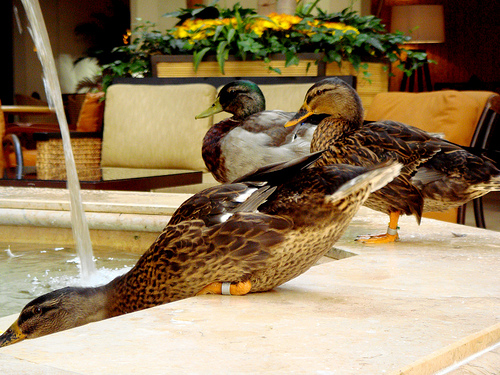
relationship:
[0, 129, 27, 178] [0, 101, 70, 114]
stand on table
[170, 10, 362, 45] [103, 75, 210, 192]
flowers on chair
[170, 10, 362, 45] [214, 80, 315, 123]
flowers on chair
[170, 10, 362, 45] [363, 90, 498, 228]
flowers on chair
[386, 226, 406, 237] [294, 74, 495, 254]
tag on duck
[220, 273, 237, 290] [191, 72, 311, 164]
tag on duck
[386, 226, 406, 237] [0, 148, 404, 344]
tag on duck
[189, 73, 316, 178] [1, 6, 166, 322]
duck standing by fountain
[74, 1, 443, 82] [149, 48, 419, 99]
greenery inside planter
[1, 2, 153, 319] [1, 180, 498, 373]
water in swimming pool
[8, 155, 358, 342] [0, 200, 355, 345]
duck drinking from pond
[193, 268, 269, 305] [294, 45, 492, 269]
leg on duck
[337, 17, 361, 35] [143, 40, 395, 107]
flower in pot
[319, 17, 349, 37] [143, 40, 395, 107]
flower in pot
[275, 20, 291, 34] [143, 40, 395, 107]
flower in pot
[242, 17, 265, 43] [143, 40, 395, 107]
flower in pot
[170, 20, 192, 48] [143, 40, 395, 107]
flower in pot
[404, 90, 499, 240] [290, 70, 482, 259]
chair behind duck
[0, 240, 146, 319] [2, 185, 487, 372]
water filling pond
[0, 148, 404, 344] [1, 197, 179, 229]
duck on ledge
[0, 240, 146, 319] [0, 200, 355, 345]
water on pond